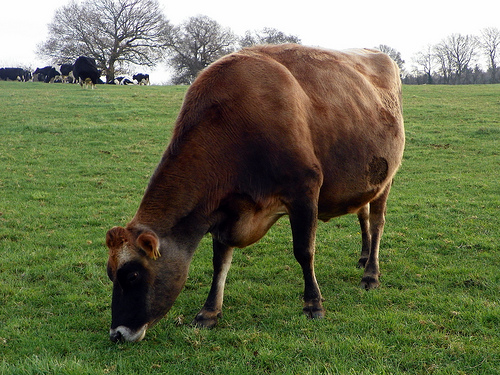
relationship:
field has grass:
[1, 85, 498, 374] [22, 110, 128, 212]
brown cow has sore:
[104, 43, 407, 343] [365, 154, 389, 188]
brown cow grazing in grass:
[104, 43, 406, 348] [8, 77, 496, 369]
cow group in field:
[2, 54, 152, 86] [1, 85, 498, 374]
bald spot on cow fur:
[360, 149, 394, 189] [178, 47, 402, 214]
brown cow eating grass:
[104, 43, 407, 343] [8, 77, 496, 369]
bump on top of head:
[103, 222, 134, 250] [97, 222, 184, 350]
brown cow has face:
[104, 43, 407, 343] [98, 221, 188, 344]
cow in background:
[133, 73, 151, 86] [2, 0, 497, 109]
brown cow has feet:
[104, 43, 407, 343] [192, 257, 237, 318]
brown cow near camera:
[104, 43, 407, 343] [1, 1, 497, 373]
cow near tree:
[135, 69, 153, 86] [57, 0, 159, 85]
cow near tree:
[114, 71, 134, 88] [57, 0, 159, 85]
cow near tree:
[67, 56, 99, 84] [161, 5, 235, 75]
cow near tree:
[37, 69, 59, 85] [161, 5, 235, 75]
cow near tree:
[58, 56, 73, 82] [161, 5, 235, 75]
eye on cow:
[116, 260, 158, 284] [75, 56, 417, 311]